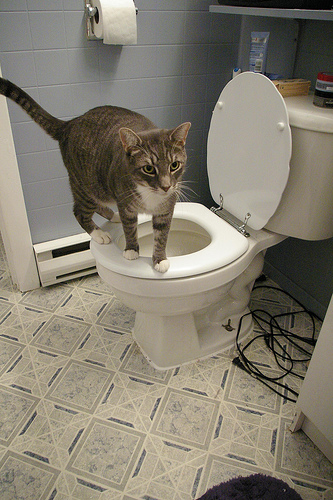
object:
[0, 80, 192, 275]
cat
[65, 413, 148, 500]
tile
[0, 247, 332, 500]
floor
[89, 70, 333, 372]
toilet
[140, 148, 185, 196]
face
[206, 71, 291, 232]
lid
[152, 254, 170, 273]
paw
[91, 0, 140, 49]
toilet paper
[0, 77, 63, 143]
tail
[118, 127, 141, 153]
ear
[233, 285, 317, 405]
cord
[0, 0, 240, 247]
wall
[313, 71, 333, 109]
bottle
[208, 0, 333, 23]
shelf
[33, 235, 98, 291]
vent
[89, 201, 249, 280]
seat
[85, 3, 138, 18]
holder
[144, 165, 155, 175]
eye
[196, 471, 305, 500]
rug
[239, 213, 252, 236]
hinge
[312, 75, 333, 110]
toiletry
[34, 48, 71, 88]
tile